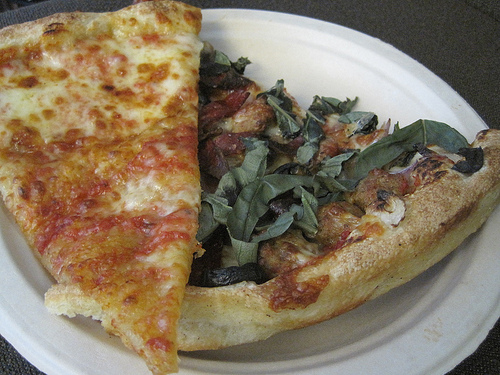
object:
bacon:
[265, 95, 302, 135]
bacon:
[309, 92, 355, 118]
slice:
[171, 32, 496, 358]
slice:
[1, 0, 207, 374]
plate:
[0, 6, 497, 375]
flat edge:
[0, 337, 45, 375]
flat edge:
[449, 324, 500, 375]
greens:
[225, 173, 307, 273]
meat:
[199, 90, 251, 170]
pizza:
[0, 0, 500, 371]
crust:
[169, 246, 370, 334]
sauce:
[37, 169, 128, 251]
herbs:
[213, 97, 462, 231]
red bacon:
[196, 87, 252, 119]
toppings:
[261, 99, 398, 203]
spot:
[277, 279, 311, 303]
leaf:
[248, 211, 296, 247]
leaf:
[215, 145, 271, 207]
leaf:
[318, 149, 356, 179]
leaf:
[344, 118, 472, 183]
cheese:
[0, 0, 212, 373]